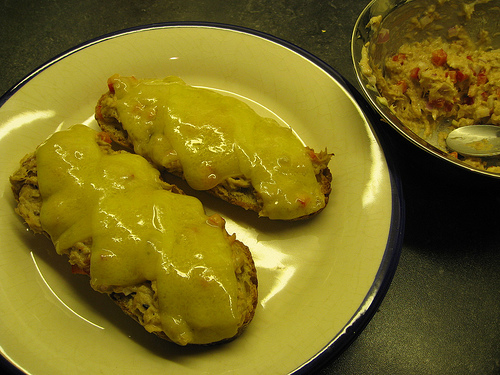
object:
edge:
[346, 0, 484, 180]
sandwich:
[91, 73, 345, 216]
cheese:
[130, 85, 313, 201]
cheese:
[40, 137, 242, 344]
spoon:
[450, 113, 499, 159]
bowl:
[350, 3, 500, 177]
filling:
[361, 4, 496, 165]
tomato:
[432, 47, 447, 65]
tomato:
[393, 52, 406, 64]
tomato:
[447, 70, 464, 84]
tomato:
[434, 100, 456, 112]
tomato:
[475, 73, 489, 89]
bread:
[94, 78, 332, 218]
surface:
[5, 4, 499, 372]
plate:
[4, 23, 398, 374]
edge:
[2, 21, 55, 371]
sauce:
[40, 76, 326, 311]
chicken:
[15, 76, 338, 343]